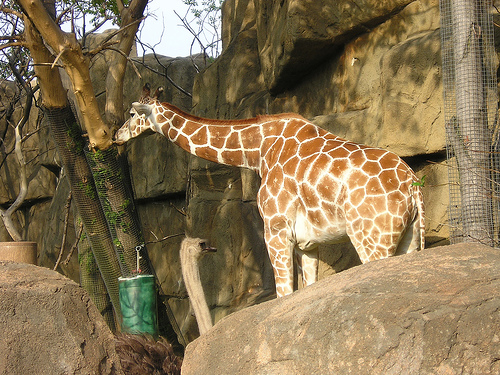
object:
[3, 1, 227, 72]
sky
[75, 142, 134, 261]
vines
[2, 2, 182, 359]
tree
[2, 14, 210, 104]
branches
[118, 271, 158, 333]
bucket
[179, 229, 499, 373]
rock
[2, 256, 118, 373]
rock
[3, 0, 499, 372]
enclosure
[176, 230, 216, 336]
ostrich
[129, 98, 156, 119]
ear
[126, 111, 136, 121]
eye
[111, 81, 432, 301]
giraffe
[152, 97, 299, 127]
hair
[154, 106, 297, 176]
neck